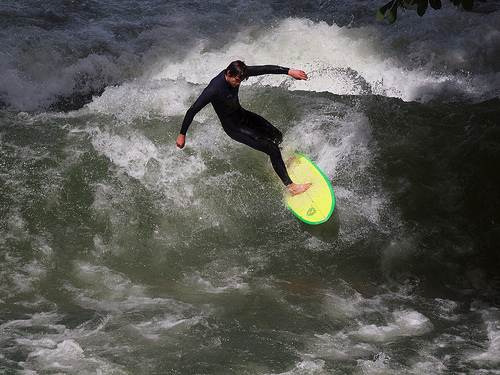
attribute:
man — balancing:
[174, 60, 312, 197]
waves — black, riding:
[0, 0, 499, 290]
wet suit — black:
[179, 59, 294, 186]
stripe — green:
[308, 159, 350, 219]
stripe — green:
[278, 201, 318, 234]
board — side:
[278, 149, 336, 231]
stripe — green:
[311, 182, 350, 246]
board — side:
[288, 155, 339, 237]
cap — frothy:
[87, 75, 204, 131]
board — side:
[244, 122, 359, 257]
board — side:
[277, 149, 340, 229]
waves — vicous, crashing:
[67, 69, 494, 286]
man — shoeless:
[113, 36, 361, 228]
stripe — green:
[277, 148, 340, 228]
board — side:
[269, 147, 337, 227]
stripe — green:
[281, 153, 338, 227]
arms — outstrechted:
[173, 62, 310, 150]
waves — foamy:
[6, 78, 497, 227]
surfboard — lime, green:
[280, 152, 338, 226]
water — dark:
[0, 3, 499, 370]